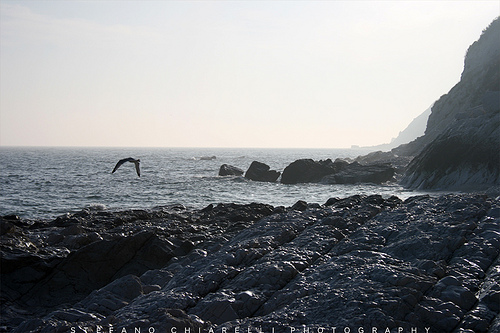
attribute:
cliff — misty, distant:
[369, 91, 434, 220]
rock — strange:
[212, 158, 247, 182]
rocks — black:
[18, 198, 498, 323]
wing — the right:
[134, 162, 143, 177]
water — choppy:
[13, 155, 116, 199]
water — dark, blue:
[57, 152, 98, 206]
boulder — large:
[217, 159, 242, 189]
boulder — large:
[244, 158, 276, 189]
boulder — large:
[282, 157, 391, 193]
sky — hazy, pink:
[2, 1, 499, 146]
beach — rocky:
[2, 190, 499, 331]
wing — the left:
[107, 161, 124, 174]